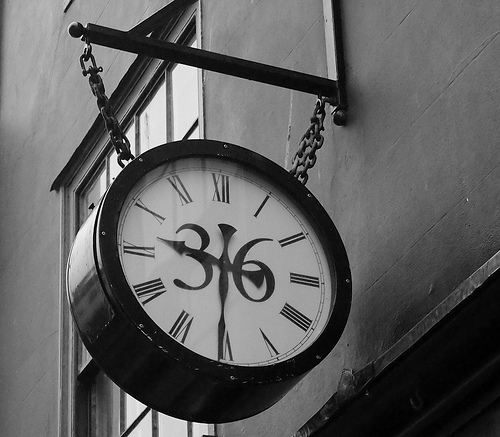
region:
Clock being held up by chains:
[75, 138, 342, 393]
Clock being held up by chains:
[87, 109, 384, 224]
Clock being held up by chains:
[153, 133, 368, 305]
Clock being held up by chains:
[78, 137, 199, 260]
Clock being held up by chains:
[226, 124, 358, 259]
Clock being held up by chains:
[258, 106, 345, 230]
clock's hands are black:
[161, 216, 260, 350]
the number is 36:
[157, 210, 282, 335]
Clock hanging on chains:
[110, 131, 369, 396]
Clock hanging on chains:
[58, 41, 414, 430]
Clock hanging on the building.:
[96, 140, 346, 381]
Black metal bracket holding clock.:
[62, 2, 358, 126]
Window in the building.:
[45, 0, 233, 435]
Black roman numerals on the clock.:
[120, 145, 327, 362]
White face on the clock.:
[112, 152, 339, 369]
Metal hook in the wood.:
[405, 381, 425, 414]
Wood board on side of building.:
[302, 235, 497, 435]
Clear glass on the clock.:
[119, 149, 331, 377]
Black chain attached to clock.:
[285, 92, 355, 190]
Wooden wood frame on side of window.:
[54, 181, 81, 435]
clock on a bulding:
[51, 125, 386, 428]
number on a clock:
[276, 291, 306, 336]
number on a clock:
[255, 317, 282, 363]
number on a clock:
[215, 315, 236, 366]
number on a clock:
[151, 290, 197, 341]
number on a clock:
[125, 262, 177, 307]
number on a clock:
[115, 223, 160, 256]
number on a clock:
[131, 190, 162, 230]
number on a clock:
[161, 162, 189, 214]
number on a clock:
[199, 160, 233, 215]